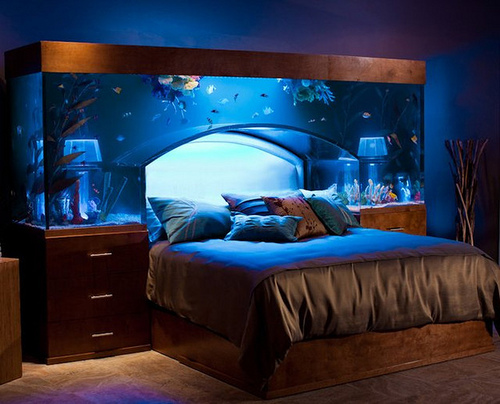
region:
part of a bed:
[361, 263, 381, 276]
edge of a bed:
[262, 245, 284, 315]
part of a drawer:
[118, 294, 157, 318]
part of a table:
[88, 297, 100, 307]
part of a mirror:
[399, 126, 413, 178]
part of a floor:
[157, 376, 172, 388]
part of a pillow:
[228, 200, 247, 223]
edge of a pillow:
[278, 185, 296, 230]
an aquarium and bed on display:
[5, 35, 499, 400]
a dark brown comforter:
[149, 220, 498, 383]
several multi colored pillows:
[147, 190, 358, 244]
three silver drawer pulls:
[86, 244, 116, 342]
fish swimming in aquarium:
[14, 70, 427, 227]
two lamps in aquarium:
[50, 123, 394, 225]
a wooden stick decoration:
[438, 128, 493, 249]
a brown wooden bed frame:
[147, 302, 499, 402]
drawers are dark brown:
[14, 213, 152, 365]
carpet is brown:
[2, 323, 499, 400]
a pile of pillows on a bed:
[205, 197, 337, 241]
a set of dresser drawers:
[38, 225, 160, 360]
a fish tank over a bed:
[131, 80, 372, 235]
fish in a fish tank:
[206, 85, 273, 113]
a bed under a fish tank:
[166, 107, 401, 350]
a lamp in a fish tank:
[352, 130, 390, 202]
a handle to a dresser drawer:
[89, 290, 116, 303]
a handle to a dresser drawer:
[86, 247, 116, 263]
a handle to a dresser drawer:
[85, 329, 120, 340]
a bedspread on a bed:
[258, 257, 340, 359]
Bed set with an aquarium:
[4, 43, 496, 396]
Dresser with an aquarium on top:
[1, 40, 426, 365]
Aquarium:
[4, 39, 424, 229]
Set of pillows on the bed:
[149, 184, 356, 244]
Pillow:
[149, 197, 232, 244]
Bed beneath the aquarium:
[146, 185, 498, 400]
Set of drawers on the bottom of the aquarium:
[0, 220, 152, 367]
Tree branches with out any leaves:
[444, 135, 491, 248]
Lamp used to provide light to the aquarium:
[357, 133, 390, 201]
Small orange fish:
[111, 85, 125, 98]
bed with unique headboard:
[6, 41, 498, 397]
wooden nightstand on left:
[19, 223, 149, 366]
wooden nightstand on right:
[355, 204, 424, 233]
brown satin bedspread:
[145, 223, 498, 378]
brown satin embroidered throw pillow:
[261, 195, 328, 242]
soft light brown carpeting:
[0, 348, 498, 403]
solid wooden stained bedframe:
[150, 303, 495, 398]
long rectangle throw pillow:
[225, 209, 302, 243]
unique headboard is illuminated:
[7, 71, 422, 228]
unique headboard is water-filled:
[5, 70, 425, 229]